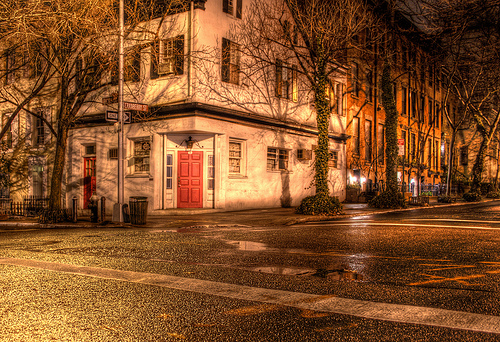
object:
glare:
[349, 214, 374, 219]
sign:
[397, 139, 406, 146]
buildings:
[452, 125, 500, 198]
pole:
[114, 0, 132, 230]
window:
[278, 158, 287, 171]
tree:
[226, 0, 383, 217]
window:
[221, 49, 230, 83]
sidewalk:
[2, 193, 500, 227]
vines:
[296, 77, 345, 214]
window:
[281, 65, 291, 99]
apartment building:
[0, 0, 354, 214]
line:
[0, 255, 500, 336]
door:
[177, 150, 202, 207]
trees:
[0, 0, 219, 225]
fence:
[0, 194, 49, 218]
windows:
[173, 35, 186, 77]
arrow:
[105, 109, 120, 121]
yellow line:
[286, 218, 500, 234]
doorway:
[175, 149, 204, 210]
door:
[83, 157, 98, 210]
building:
[0, 0, 351, 215]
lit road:
[0, 198, 500, 341]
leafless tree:
[366, 49, 423, 207]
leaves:
[302, 182, 314, 191]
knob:
[177, 182, 184, 190]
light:
[185, 146, 195, 156]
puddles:
[42, 236, 64, 247]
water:
[312, 267, 363, 283]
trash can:
[126, 194, 149, 228]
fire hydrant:
[86, 193, 100, 223]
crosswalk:
[0, 225, 500, 341]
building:
[347, 0, 464, 204]